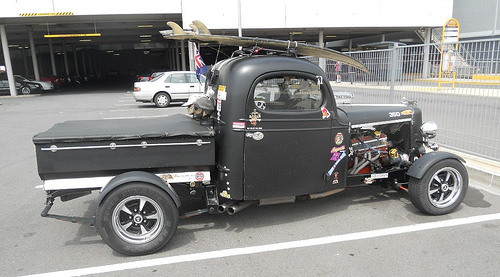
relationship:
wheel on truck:
[95, 182, 178, 255] [32, 55, 439, 216]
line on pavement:
[1, 212, 499, 277] [1, 82, 499, 277]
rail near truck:
[296, 38, 499, 195] [32, 55, 439, 216]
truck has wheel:
[32, 55, 439, 216] [407, 158, 469, 216]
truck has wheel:
[32, 55, 439, 216] [95, 182, 178, 255]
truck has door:
[32, 55, 439, 216] [244, 72, 332, 198]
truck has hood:
[32, 55, 439, 216] [338, 103, 413, 128]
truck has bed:
[32, 55, 439, 216] [33, 118, 215, 180]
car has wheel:
[134, 71, 205, 108] [153, 93, 171, 108]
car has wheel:
[1, 76, 43, 95] [21, 87, 32, 95]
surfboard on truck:
[164, 21, 372, 75] [32, 55, 439, 216]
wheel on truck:
[407, 158, 469, 216] [32, 55, 439, 216]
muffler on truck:
[217, 198, 297, 213] [32, 55, 439, 216]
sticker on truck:
[334, 132, 344, 143] [32, 55, 439, 216]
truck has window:
[32, 55, 439, 216] [251, 75, 326, 115]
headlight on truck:
[420, 122, 441, 152] [32, 55, 439, 216]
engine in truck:
[349, 129, 410, 178] [32, 55, 439, 216]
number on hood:
[389, 111, 400, 118] [338, 103, 413, 128]